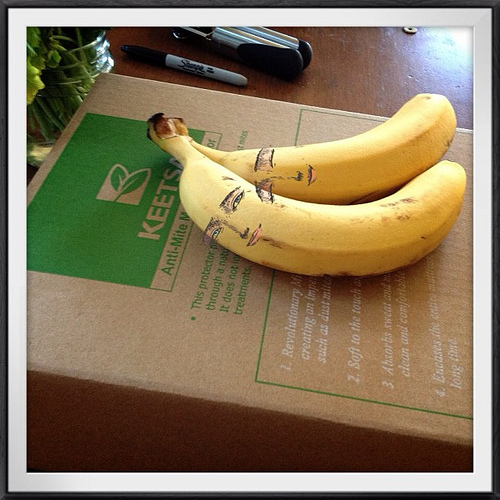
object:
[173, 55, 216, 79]
sharpie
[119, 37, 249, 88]
marker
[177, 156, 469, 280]
banana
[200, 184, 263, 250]
face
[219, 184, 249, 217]
eyes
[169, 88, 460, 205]
banana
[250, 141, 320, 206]
face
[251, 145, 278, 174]
eyes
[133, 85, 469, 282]
two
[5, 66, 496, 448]
box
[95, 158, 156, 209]
logo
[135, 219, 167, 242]
k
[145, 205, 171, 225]
e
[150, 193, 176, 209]
e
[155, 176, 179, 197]
t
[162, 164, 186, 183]
s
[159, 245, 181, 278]
anti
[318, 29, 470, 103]
table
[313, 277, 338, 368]
writing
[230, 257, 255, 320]
writing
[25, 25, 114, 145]
glass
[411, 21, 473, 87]
reflection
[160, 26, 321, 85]
stapler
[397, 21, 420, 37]
button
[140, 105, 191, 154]
stem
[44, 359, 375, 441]
side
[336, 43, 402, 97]
desk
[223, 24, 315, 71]
pens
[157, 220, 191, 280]
print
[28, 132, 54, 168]
water